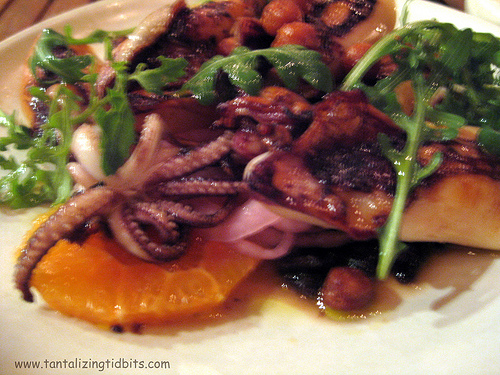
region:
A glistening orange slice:
[46, 247, 214, 325]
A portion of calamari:
[92, 122, 229, 268]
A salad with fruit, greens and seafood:
[5, 19, 485, 327]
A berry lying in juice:
[314, 265, 381, 324]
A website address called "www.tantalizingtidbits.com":
[3, 356, 180, 372]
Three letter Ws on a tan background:
[8, 358, 44, 374]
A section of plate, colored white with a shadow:
[431, 263, 498, 322]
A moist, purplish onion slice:
[224, 203, 296, 264]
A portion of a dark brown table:
[2, 4, 43, 24]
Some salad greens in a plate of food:
[154, 39, 333, 113]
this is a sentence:
[10, 340, 187, 373]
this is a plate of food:
[32, 10, 497, 345]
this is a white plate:
[1, 0, 482, 374]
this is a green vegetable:
[346, 15, 497, 336]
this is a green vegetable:
[0, 86, 191, 203]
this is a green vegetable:
[189, 15, 325, 170]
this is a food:
[37, 25, 379, 347]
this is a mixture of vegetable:
[38, 16, 497, 328]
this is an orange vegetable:
[43, 242, 273, 344]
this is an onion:
[210, 190, 307, 265]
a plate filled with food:
[3, 1, 499, 373]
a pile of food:
[1, 2, 497, 367]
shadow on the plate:
[420, 256, 499, 329]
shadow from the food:
[408, 238, 498, 327]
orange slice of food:
[16, 210, 263, 335]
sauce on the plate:
[318, 308, 387, 321]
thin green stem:
[370, 98, 420, 283]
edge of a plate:
[0, 0, 100, 57]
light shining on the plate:
[102, 1, 127, 9]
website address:
[8, 353, 183, 374]